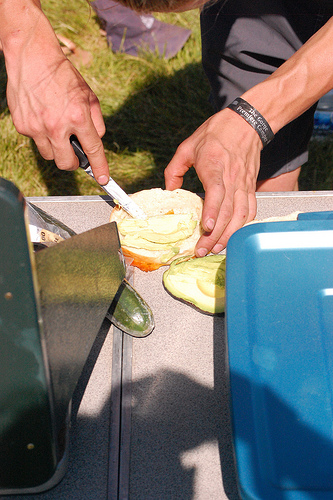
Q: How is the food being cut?
A: With a knife.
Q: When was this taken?
A: Daytime.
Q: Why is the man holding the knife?
A: To cut food.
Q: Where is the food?
A: On the table.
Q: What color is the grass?
A: Green.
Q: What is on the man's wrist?
A: A bracelet.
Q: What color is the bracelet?
A: Black.